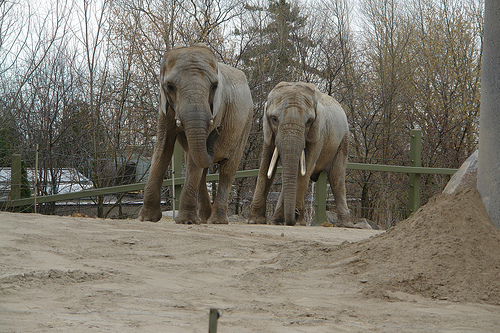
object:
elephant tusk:
[265, 148, 280, 179]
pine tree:
[228, 0, 331, 97]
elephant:
[245, 80, 355, 229]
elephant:
[138, 43, 254, 225]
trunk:
[275, 109, 308, 226]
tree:
[75, 0, 112, 219]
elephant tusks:
[300, 149, 307, 176]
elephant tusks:
[175, 116, 214, 127]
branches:
[0, 0, 244, 210]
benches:
[362, 39, 445, 213]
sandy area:
[0, 213, 500, 333]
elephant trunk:
[177, 87, 213, 169]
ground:
[0, 211, 500, 333]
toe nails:
[137, 213, 221, 224]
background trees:
[0, 0, 500, 215]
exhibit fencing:
[58, 178, 118, 204]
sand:
[0, 169, 500, 333]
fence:
[0, 129, 462, 211]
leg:
[329, 160, 352, 219]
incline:
[96, 200, 388, 271]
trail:
[88, 224, 349, 333]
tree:
[361, 0, 481, 227]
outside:
[0, 0, 221, 215]